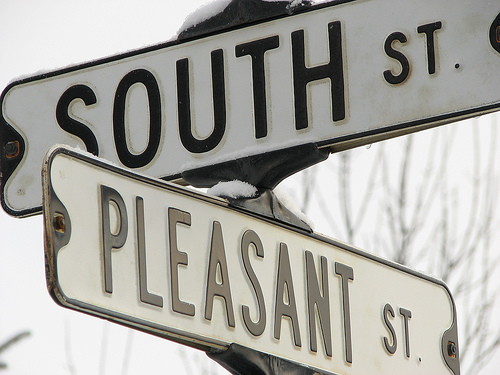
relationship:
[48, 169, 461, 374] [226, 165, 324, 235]
sign on pole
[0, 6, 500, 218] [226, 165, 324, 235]
black/white sign on pole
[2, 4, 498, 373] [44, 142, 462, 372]
wall behind sign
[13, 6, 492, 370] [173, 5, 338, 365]
black/white sign on pole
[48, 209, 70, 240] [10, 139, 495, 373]
screw fixed at end of sign board